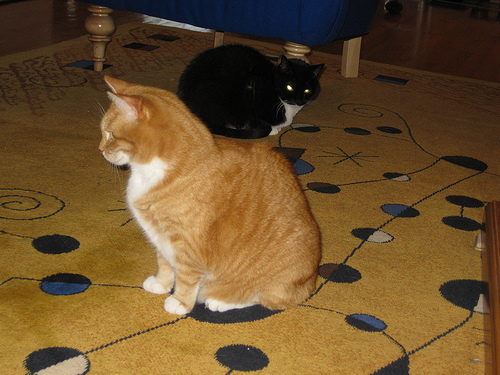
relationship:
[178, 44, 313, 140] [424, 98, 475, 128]
cat on top of floor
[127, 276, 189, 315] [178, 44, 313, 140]
paws of cat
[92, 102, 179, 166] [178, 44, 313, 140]
face attached to cat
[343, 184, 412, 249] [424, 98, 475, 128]
design on top of floor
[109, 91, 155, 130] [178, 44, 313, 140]
ear attached to cat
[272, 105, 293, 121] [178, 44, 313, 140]
whiskers attached to cat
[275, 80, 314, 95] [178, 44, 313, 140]
eyes attached to cat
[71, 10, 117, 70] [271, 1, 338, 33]
legs attached to table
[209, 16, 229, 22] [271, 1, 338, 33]
tablecloth on top of table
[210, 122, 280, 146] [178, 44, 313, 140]
tail attached to cat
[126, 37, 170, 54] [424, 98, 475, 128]
spots on top of floor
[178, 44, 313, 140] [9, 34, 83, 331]
cat facing to left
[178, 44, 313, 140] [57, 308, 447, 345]
cat facing different directions